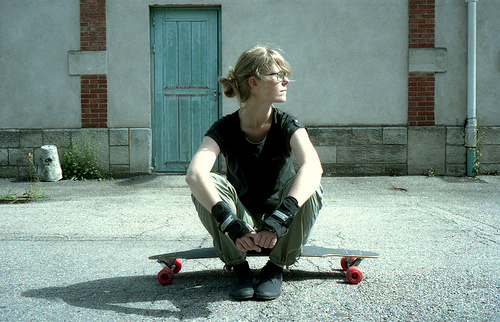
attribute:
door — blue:
[162, 24, 282, 196]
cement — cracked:
[31, 183, 181, 318]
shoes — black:
[226, 263, 288, 299]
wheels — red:
[343, 261, 368, 282]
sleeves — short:
[200, 111, 300, 143]